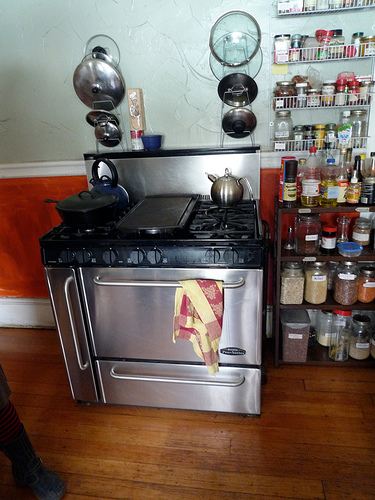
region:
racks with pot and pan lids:
[71, 0, 272, 157]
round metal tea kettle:
[205, 161, 260, 211]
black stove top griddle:
[105, 178, 207, 238]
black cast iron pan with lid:
[38, 180, 123, 231]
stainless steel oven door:
[37, 258, 270, 410]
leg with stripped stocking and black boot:
[0, 362, 60, 497]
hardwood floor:
[86, 415, 349, 490]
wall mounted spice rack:
[267, 5, 374, 155]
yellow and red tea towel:
[167, 272, 236, 374]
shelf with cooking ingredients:
[271, 147, 372, 378]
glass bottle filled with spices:
[278, 154, 303, 212]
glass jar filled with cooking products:
[275, 256, 308, 311]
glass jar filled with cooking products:
[300, 259, 331, 306]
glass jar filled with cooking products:
[329, 253, 362, 311]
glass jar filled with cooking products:
[276, 300, 321, 372]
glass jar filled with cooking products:
[326, 302, 353, 367]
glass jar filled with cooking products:
[342, 312, 372, 365]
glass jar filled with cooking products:
[355, 260, 373, 309]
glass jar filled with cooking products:
[349, 211, 372, 252]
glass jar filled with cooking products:
[292, 206, 326, 263]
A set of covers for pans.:
[211, 11, 261, 143]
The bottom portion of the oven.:
[99, 361, 260, 416]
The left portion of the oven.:
[46, 269, 96, 404]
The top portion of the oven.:
[85, 270, 258, 362]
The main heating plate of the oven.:
[120, 192, 196, 229]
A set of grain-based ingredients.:
[279, 311, 374, 359]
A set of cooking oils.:
[284, 154, 374, 204]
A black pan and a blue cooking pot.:
[56, 163, 132, 220]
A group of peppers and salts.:
[275, 23, 374, 69]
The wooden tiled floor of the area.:
[71, 414, 366, 498]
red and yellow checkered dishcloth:
[158, 266, 237, 379]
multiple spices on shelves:
[275, 154, 374, 375]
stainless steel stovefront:
[38, 242, 261, 427]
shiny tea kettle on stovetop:
[200, 164, 264, 214]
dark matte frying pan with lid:
[39, 188, 125, 231]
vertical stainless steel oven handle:
[54, 267, 93, 386]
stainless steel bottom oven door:
[88, 356, 268, 419]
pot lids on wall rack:
[198, 3, 262, 151]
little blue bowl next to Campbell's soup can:
[122, 127, 177, 154]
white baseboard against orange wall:
[2, 191, 51, 334]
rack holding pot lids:
[69, 29, 125, 155]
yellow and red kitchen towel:
[168, 276, 233, 367]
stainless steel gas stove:
[31, 153, 269, 417]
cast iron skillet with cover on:
[36, 191, 123, 230]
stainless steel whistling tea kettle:
[199, 166, 256, 214]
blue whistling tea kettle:
[83, 155, 131, 211]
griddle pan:
[118, 185, 201, 246]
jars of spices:
[271, 26, 373, 61]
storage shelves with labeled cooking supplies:
[273, 152, 373, 358]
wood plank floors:
[272, 368, 367, 489]